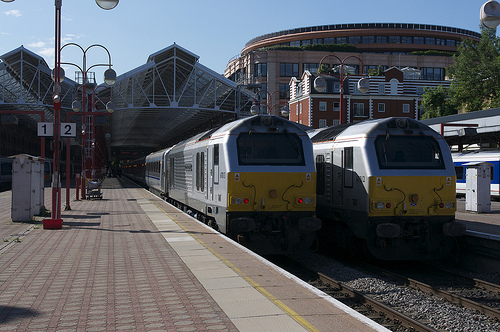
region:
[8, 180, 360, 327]
a train boarding platform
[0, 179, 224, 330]
decorative brick paver pattern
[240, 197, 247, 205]
red train engine light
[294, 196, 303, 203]
red train engine light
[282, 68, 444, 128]
red and white building in distance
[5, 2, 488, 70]
deep blue sky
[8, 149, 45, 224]
a white utility box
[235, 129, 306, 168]
a train front windshield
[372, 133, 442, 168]
a train front windshield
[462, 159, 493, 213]
a white utility box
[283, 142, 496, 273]
the trains are visible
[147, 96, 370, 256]
the trains are visible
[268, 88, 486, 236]
the trains are visible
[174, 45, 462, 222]
the trains are visible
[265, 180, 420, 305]
the trains are visible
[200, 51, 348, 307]
the trains are visible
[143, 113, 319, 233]
a silver white and blue train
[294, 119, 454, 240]
a silver white and blue train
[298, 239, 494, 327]
a set of train tracks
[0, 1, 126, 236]
a red overhead light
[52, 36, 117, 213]
a red overhead light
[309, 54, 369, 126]
a red overhead light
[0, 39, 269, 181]
a covered train station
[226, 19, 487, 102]
a large building in distance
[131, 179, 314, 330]
a long yellow line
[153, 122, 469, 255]
two passenger trains.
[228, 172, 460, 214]
front of trains are yellow.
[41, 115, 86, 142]
sign reads 1 and 2.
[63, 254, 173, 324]
square pattern for walkway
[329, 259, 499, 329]
two train tracks.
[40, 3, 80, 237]
red light pole.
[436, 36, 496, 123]
green trees.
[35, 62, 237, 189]
big train station.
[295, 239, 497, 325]
rock between the tracks.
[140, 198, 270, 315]
yellow stripe for safety.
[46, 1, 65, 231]
red lamp posts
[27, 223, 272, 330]
patterned concrete and walkway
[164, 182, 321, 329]
a painted yellow caution line along tracks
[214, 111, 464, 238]
the rear of train is silver and yellow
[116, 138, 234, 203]
windows suggest that this a commuter train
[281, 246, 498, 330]
train tracks and small stones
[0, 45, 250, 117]
a covered train station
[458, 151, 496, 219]
small white building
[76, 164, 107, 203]
a bench under a street light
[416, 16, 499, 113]
a tree with green leaves